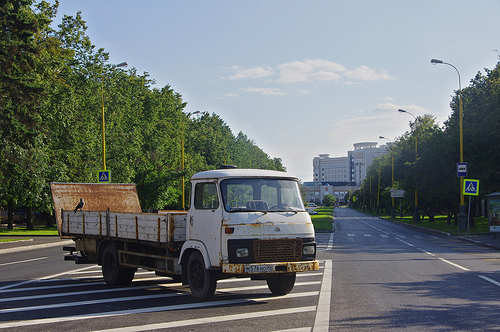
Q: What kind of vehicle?
A: Truck.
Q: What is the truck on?
A: The street.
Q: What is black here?
A: The street.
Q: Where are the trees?
A: Lining the street.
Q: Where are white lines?
A: Street.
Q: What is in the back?
A: A building.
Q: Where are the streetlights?
A: On side of road.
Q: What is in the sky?
A: Clouds.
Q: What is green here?
A: Trees.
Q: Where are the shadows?
A: On the ground.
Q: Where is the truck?
A: On the street.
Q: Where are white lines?
A: In the street.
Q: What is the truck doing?
A: Parked.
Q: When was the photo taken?
A: Daytime.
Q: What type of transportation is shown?
A: Truck.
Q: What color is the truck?
A: White.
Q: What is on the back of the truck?
A: Bird.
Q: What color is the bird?
A: Black.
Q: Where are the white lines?
A: Street.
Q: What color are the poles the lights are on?
A: Yellow.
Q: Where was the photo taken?
A: On the street.